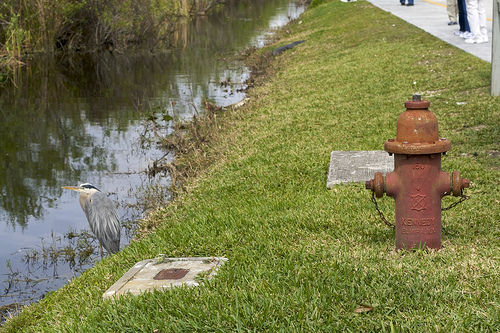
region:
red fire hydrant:
[395, 81, 451, 256]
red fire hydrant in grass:
[391, 78, 444, 253]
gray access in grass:
[128, 250, 221, 299]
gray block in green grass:
[336, 148, 365, 183]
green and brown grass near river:
[308, 15, 393, 109]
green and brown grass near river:
[225, 125, 317, 230]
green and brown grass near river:
[273, 254, 483, 314]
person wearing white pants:
[466, 7, 486, 29]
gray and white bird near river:
[53, 172, 136, 256]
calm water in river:
[0, 47, 219, 167]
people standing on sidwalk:
[400, 0, 495, 62]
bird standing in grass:
[55, 160, 144, 281]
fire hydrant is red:
[369, 69, 469, 259]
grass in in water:
[0, 19, 284, 328]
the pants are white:
[460, 2, 492, 47]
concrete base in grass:
[308, 114, 426, 217]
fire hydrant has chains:
[344, 148, 472, 237]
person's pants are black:
[453, 0, 470, 30]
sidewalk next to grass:
[370, 0, 493, 70]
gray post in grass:
[490, 0, 498, 102]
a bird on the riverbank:
[52, 170, 137, 271]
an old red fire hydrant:
[343, 69, 480, 267]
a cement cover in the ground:
[107, 254, 234, 304]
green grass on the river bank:
[263, 70, 363, 155]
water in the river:
[25, 39, 187, 159]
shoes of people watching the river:
[431, 0, 493, 43]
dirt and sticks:
[146, 65, 266, 206]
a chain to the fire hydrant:
[369, 192, 396, 225]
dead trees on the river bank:
[34, 2, 194, 64]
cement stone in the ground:
[316, 129, 405, 206]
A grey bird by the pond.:
[62, 175, 127, 256]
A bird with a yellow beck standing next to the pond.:
[57, 174, 129, 259]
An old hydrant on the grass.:
[364, 90, 475, 256]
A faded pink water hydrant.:
[363, 90, 472, 257]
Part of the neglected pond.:
[8, 40, 135, 281]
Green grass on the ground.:
[154, 9, 466, 325]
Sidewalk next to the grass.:
[371, 1, 497, 68]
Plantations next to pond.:
[2, 5, 182, 63]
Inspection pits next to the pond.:
[103, 244, 230, 298]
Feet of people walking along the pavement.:
[409, 0, 491, 64]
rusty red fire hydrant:
[363, 82, 476, 267]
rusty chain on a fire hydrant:
[360, 173, 394, 238]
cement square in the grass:
[100, 247, 235, 307]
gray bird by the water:
[51, 172, 132, 261]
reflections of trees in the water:
[11, 48, 133, 176]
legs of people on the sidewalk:
[438, 3, 490, 51]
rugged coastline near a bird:
[148, 102, 240, 179]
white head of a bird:
[52, 172, 99, 210]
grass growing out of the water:
[20, 227, 85, 285]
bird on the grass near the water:
[27, 61, 319, 308]